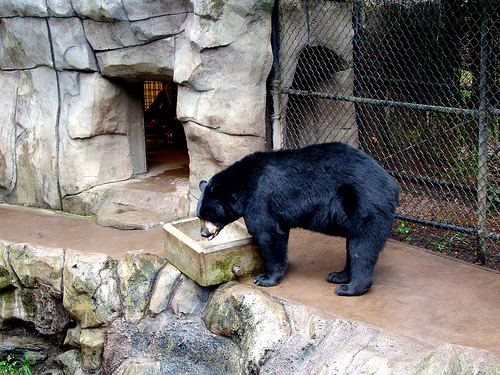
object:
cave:
[67, 43, 193, 209]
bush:
[1, 355, 31, 375]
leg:
[241, 215, 289, 273]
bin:
[161, 215, 263, 287]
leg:
[348, 222, 388, 287]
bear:
[195, 141, 401, 297]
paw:
[253, 270, 280, 287]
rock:
[0, 0, 356, 235]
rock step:
[93, 170, 194, 233]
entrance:
[279, 43, 366, 153]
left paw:
[335, 284, 367, 295]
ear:
[199, 179, 207, 192]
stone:
[0, 0, 366, 235]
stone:
[0, 242, 499, 374]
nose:
[200, 228, 210, 239]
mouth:
[204, 230, 219, 241]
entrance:
[86, 62, 190, 187]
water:
[184, 228, 221, 241]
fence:
[267, 0, 500, 270]